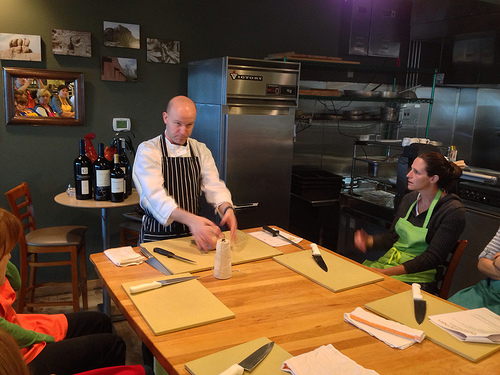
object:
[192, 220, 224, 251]
meat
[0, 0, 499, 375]
room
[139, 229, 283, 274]
cutting board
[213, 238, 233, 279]
spindle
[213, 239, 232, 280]
white string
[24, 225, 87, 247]
seat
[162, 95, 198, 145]
man's head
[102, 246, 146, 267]
towel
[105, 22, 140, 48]
mountain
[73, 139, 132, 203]
wine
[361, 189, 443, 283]
apron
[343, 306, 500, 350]
papers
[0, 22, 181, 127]
picture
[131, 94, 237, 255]
man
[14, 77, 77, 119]
photo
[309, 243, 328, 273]
butcher knife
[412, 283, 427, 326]
butcher knife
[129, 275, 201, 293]
butcher knife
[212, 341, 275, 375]
butcher knife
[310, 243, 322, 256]
handle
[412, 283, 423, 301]
handle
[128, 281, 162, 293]
handle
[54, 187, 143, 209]
table top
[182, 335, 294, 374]
cutting boards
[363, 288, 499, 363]
cutting boards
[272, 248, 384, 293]
cutting boards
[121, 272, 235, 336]
board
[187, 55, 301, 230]
commercial fridge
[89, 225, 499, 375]
table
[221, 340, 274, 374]
knives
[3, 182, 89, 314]
chair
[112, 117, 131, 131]
thermostat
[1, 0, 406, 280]
wall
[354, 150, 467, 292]
person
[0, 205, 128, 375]
person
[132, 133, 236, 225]
shirt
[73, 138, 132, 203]
bottles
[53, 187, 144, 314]
table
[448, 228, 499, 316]
person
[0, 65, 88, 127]
frame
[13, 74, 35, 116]
person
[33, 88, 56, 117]
person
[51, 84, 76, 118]
person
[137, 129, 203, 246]
apron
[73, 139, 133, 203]
wine bottle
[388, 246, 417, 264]
tie